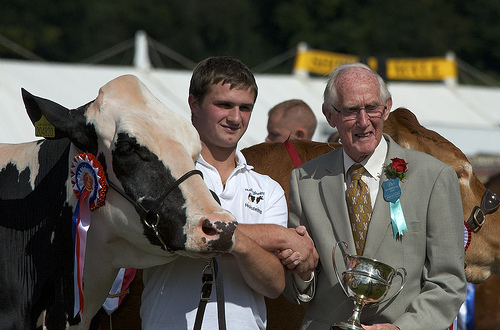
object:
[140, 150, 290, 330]
shirt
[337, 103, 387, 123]
eyeglasses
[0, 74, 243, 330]
cow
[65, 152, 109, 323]
ribbon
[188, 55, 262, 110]
hair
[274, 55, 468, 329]
man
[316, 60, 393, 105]
hair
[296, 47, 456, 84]
banner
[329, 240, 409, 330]
trophy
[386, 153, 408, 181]
rose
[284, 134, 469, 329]
coat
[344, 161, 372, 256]
tie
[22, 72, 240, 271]
head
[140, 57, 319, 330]
boy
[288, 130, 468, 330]
suit